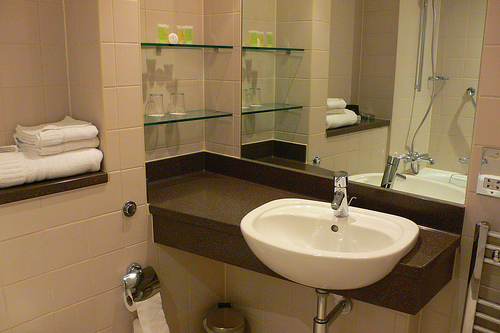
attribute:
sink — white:
[238, 194, 423, 293]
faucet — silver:
[331, 169, 355, 220]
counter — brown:
[158, 166, 240, 258]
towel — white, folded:
[3, 152, 105, 180]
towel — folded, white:
[23, 114, 99, 137]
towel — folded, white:
[25, 135, 100, 155]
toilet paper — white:
[127, 293, 170, 332]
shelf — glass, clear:
[145, 107, 234, 130]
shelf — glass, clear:
[145, 36, 234, 57]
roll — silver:
[129, 266, 162, 299]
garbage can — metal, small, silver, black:
[208, 308, 243, 333]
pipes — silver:
[315, 291, 344, 332]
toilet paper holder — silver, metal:
[122, 258, 163, 304]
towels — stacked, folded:
[3, 121, 103, 179]